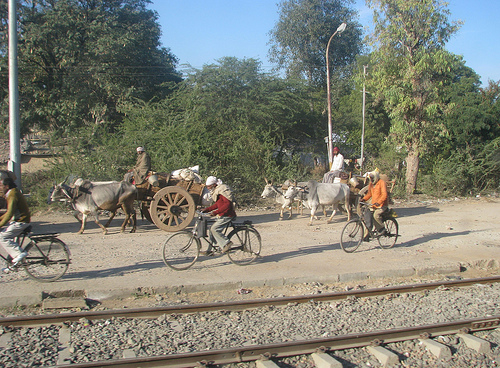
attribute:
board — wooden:
[456, 333, 491, 359]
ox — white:
[261, 179, 361, 220]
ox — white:
[275, 174, 351, 228]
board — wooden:
[415, 335, 460, 357]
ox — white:
[54, 177, 144, 234]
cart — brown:
[110, 167, 237, 229]